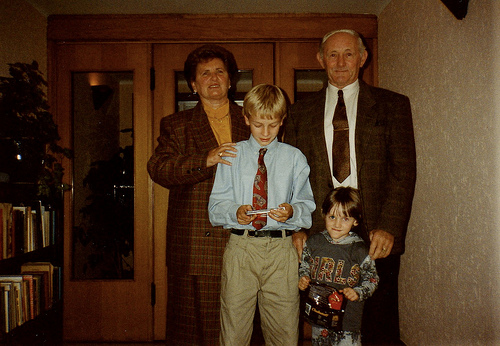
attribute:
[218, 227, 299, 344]
pants — brown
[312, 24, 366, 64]
hair — grey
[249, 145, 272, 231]
tie — red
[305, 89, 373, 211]
tie — brown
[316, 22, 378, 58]
hair — short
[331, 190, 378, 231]
hair — short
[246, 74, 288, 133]
hair — short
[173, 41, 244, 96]
hair — short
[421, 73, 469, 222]
wall — beige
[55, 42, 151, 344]
door — wooden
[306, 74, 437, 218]
shirt — white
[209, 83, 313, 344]
boy — blonde-haired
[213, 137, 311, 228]
shirt — blue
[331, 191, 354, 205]
hair — blond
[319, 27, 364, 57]
gray hair — grey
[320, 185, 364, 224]
hair — short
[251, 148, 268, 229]
tie — red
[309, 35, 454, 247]
man — smiling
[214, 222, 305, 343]
pants — tan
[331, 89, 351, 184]
tie — brown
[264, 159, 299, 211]
shirt — blue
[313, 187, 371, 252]
girl hair — blond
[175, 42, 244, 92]
hair — short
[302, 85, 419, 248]
jacket — brown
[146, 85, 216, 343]
jacket — plaid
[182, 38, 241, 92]
hair — brown